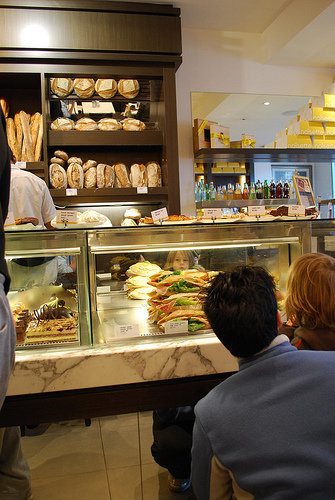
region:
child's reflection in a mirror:
[154, 246, 198, 279]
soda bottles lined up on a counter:
[190, 174, 295, 199]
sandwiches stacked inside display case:
[143, 266, 208, 332]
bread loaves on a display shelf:
[45, 148, 166, 189]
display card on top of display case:
[146, 204, 168, 223]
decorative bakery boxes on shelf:
[272, 92, 333, 150]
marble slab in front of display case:
[10, 345, 226, 395]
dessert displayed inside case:
[19, 293, 79, 346]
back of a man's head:
[194, 254, 322, 479]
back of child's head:
[285, 243, 333, 330]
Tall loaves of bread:
[5, 101, 51, 165]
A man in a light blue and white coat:
[165, 333, 332, 495]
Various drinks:
[185, 169, 305, 205]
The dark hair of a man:
[199, 257, 286, 356]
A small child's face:
[158, 245, 202, 275]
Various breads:
[48, 64, 173, 199]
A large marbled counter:
[1, 329, 252, 391]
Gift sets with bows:
[193, 112, 263, 159]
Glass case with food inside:
[5, 212, 299, 337]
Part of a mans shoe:
[150, 455, 201, 491]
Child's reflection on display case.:
[158, 239, 200, 278]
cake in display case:
[26, 307, 80, 354]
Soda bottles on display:
[196, 170, 300, 199]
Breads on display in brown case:
[8, 74, 171, 190]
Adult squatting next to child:
[147, 230, 334, 466]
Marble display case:
[2, 233, 334, 400]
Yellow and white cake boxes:
[257, 84, 334, 156]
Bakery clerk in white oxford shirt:
[2, 127, 67, 251]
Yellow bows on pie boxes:
[195, 113, 259, 153]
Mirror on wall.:
[188, 70, 333, 213]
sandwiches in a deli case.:
[149, 263, 203, 335]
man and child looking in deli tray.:
[209, 243, 332, 333]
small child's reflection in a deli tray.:
[162, 252, 198, 275]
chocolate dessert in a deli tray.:
[26, 292, 83, 332]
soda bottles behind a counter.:
[198, 171, 303, 200]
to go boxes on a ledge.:
[271, 93, 334, 163]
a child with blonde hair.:
[278, 249, 333, 322]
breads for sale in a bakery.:
[50, 152, 169, 192]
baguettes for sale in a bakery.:
[4, 98, 44, 166]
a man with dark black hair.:
[193, 300, 295, 356]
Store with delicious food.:
[1, 68, 333, 343]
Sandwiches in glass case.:
[146, 270, 220, 334]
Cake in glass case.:
[23, 312, 84, 348]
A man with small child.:
[190, 256, 333, 497]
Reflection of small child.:
[163, 247, 202, 271]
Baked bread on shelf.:
[50, 146, 166, 185]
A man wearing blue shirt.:
[181, 344, 331, 492]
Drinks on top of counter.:
[194, 179, 309, 203]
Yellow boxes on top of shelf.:
[269, 96, 332, 147]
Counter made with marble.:
[19, 332, 225, 399]